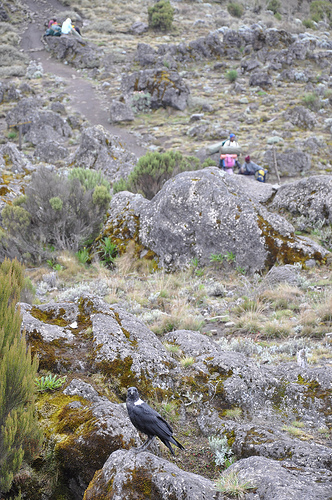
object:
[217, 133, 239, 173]
hikers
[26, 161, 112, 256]
large boulder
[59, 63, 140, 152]
trail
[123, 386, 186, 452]
black bird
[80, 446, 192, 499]
rock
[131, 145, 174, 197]
scrub brush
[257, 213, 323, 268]
green moss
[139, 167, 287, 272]
rocks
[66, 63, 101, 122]
path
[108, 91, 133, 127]
rocks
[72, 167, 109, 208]
green bushes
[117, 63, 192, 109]
rock wall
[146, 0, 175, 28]
tree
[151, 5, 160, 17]
leaves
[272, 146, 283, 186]
brown stick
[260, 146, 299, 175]
rock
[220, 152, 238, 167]
pink backpack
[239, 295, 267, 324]
grey bush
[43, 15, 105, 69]
mountianside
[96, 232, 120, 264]
grass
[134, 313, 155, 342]
dry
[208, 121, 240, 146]
focus